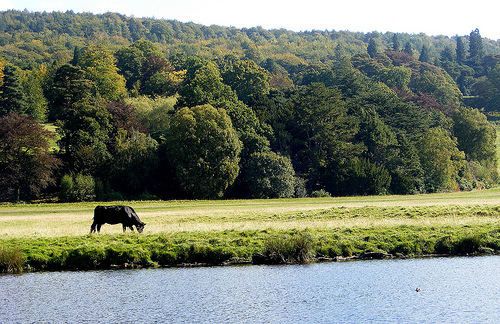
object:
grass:
[0, 209, 78, 230]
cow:
[82, 197, 150, 237]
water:
[1, 250, 498, 320]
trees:
[340, 69, 488, 223]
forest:
[3, 36, 484, 182]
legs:
[127, 224, 135, 235]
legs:
[120, 222, 130, 232]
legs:
[96, 222, 105, 232]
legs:
[87, 221, 97, 235]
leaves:
[204, 61, 290, 153]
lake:
[6, 281, 498, 322]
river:
[0, 243, 499, 322]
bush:
[270, 231, 317, 262]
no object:
[13, 14, 487, 322]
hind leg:
[84, 218, 97, 237]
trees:
[332, 85, 447, 185]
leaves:
[434, 140, 456, 160]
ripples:
[144, 293, 195, 305]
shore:
[1, 224, 499, 274]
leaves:
[114, 106, 131, 122]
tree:
[161, 102, 243, 199]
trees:
[2, 37, 156, 197]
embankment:
[1, 227, 499, 268]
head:
[133, 219, 148, 235]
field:
[155, 200, 493, 224]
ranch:
[0, 184, 499, 274]